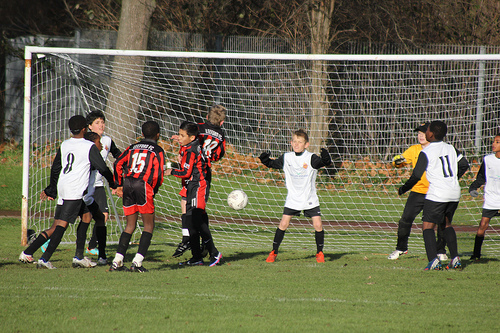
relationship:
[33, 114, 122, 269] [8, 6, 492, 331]
boys are playing soccer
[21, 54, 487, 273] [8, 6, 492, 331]
net for soccer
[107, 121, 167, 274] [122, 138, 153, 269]
boys wearing uniform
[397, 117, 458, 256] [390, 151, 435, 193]
goalie wearing a shirt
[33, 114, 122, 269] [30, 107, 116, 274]
boys wearing a uniform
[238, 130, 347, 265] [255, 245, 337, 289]
boy wearing shoes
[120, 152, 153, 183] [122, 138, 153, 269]
15 on uniform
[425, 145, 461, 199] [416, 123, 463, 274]
11 on uniform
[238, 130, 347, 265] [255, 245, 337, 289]
boy has on shoes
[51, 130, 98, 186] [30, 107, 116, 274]
8 on uniform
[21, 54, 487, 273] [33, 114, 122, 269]
net behind boys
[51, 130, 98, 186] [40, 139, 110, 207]
8 on jersey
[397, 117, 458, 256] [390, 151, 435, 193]
goalie has a shirt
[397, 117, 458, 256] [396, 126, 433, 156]
goalie wearing a hat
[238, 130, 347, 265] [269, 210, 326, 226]
boy wearing shorts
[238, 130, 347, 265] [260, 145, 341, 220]
boy wearing a shirt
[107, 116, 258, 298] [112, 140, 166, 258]
boys are wearing uniform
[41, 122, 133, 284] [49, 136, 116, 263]
boys are wearing uniform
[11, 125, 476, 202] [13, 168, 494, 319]
leaves are on grass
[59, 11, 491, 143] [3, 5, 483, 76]
trees in background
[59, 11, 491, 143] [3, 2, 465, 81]
trees in background